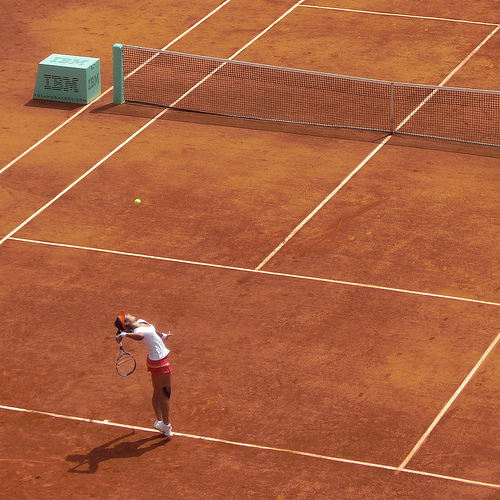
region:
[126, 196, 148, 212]
A small tennis ball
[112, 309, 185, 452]
A woman playing tennis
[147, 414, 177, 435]
White tennis sport shoes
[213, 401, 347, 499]
A brown markerd tennis field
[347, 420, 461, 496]
A brown markerd tennis field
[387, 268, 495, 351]
A brown markerd tennis field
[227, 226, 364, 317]
A brown markerd tennis field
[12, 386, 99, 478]
A brown markerd tennis field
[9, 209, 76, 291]
A brown markerd tennis field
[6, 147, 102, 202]
A brown markerd tennis field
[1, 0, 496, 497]
red clay tennis court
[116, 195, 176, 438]
woman serving the ball in a tennis match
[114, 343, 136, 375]
blue tennis racket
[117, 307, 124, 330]
orange tennis visor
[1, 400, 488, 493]
white chalk service line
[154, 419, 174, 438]
white tennis shoes behind service line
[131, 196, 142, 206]
yellow tennis ball is in the air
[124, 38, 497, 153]
black and white tennis net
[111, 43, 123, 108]
green post for holding tennis net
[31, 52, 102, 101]
box beside net advertising IBM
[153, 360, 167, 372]
the skirt is pink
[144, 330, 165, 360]
the shirt is white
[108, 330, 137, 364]
she is holding the racket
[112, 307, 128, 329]
the visor is orange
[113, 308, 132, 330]
she is wearing a visor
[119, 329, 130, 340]
the wristband is white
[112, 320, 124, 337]
her hair is in a ponytail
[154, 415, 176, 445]
the shoes are white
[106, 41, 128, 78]
the pole is teal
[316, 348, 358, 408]
the court is brown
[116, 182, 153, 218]
Tennis ball flying through the air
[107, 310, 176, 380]
Woman swinging a tennis racquet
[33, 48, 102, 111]
Green box with corporate logo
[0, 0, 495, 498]
Red clay tennis court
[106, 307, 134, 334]
Red visor on woman's head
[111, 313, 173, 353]
Woman wearing white wrist bands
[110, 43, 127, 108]
Green tennis net frame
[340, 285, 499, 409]
Foot prints on tennis court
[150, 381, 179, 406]
Tennis player's knee brace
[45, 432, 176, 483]
Shadow of tennis player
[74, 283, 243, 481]
THE LADY IS STRETCHING HERSELF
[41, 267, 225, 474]
she is playing tennis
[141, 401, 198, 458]
the shoes are white in colour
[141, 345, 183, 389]
her dress is red in colour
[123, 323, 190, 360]
her blouse is white in colour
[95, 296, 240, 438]
she is raising the racket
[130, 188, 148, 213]
the ball is in the air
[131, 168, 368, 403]
the floor is brown in colour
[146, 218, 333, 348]
the court is stripped